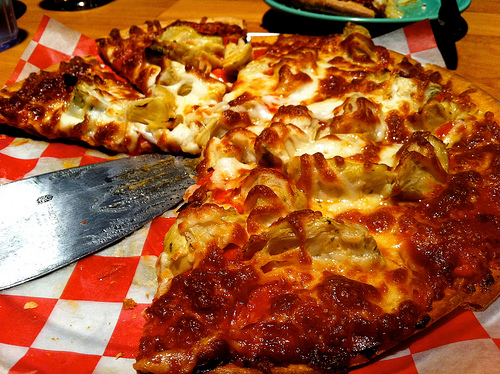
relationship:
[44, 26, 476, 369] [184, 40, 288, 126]
pizza has cheese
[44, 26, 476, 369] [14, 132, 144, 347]
pizza on paper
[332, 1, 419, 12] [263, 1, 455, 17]
food on plate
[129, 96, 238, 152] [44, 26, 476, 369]
chicken on pizza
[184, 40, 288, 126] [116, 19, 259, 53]
cheese on crust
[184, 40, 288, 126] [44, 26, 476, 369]
cheese on pizza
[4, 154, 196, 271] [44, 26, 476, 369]
utensil for pizza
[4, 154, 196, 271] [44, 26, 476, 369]
utensil near pizza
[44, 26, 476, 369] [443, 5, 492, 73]
pizza on table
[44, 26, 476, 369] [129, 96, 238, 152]
pizza has chicken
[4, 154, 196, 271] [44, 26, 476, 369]
utensil under pizza